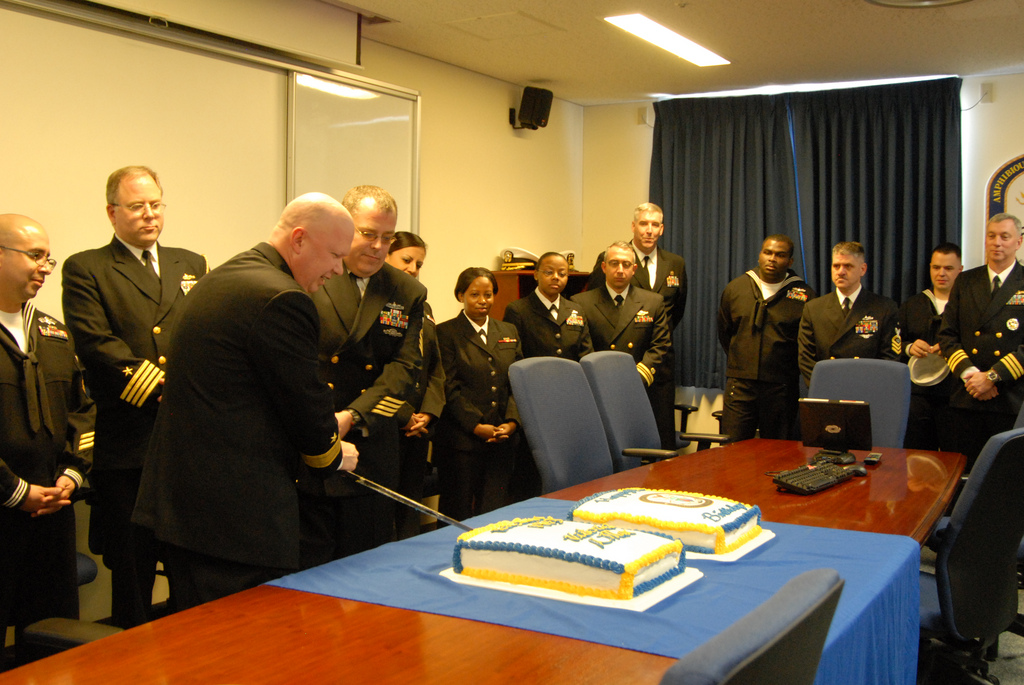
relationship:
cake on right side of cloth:
[454, 517, 702, 606] [277, 497, 923, 684]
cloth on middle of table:
[295, 479, 944, 680] [1, 434, 962, 684]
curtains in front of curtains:
[642, 92, 971, 397] [649, 77, 961, 390]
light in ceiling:
[596, 13, 729, 77] [8, 34, 1020, 145]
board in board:
[287, 69, 421, 236] [287, 69, 421, 236]